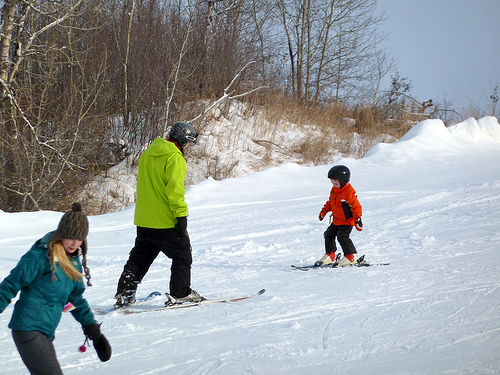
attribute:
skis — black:
[292, 258, 392, 270]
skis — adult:
[97, 286, 266, 315]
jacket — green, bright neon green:
[134, 136, 189, 230]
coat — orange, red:
[320, 183, 362, 225]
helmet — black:
[327, 163, 350, 188]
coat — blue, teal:
[1, 229, 98, 332]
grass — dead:
[31, 83, 427, 214]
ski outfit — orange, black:
[318, 180, 363, 262]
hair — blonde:
[52, 240, 84, 282]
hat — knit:
[47, 201, 94, 287]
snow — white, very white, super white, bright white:
[1, 115, 499, 374]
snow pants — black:
[324, 223, 358, 255]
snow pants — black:
[116, 225, 192, 299]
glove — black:
[83, 320, 112, 362]